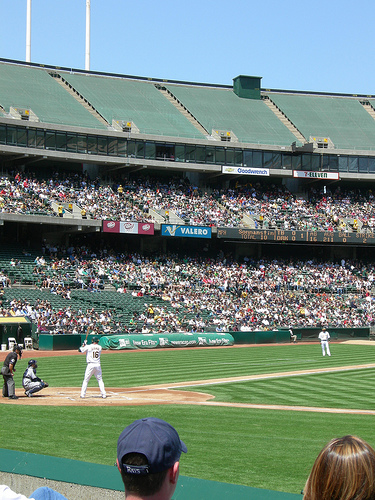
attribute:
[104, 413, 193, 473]
cap — blue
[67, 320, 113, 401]
player — waiting, ready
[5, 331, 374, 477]
field — large, green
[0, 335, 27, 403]
umpire — ready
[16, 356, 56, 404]
catcher — ready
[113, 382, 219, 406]
lines — white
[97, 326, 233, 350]
advertisement — green, long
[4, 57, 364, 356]
baseball stadium — large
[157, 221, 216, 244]
sign — advertisement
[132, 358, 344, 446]
grass — fresh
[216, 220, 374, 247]
scoreboard — high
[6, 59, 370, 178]
skybox seats — high